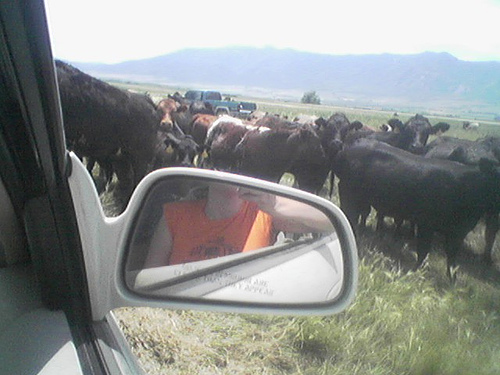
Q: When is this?
A: Daytime.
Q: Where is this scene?
A: In a cow field.